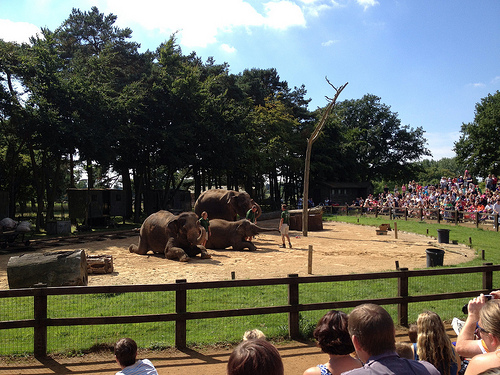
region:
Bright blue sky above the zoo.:
[387, 12, 469, 84]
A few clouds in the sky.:
[242, 4, 330, 50]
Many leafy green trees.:
[32, 6, 299, 188]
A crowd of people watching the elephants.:
[367, 171, 498, 223]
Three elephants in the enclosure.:
[122, 178, 281, 273]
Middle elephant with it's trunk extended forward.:
[202, 212, 282, 253]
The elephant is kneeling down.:
[124, 190, 213, 268]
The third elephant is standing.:
[193, 178, 264, 220]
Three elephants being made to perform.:
[125, 174, 280, 275]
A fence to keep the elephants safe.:
[93, 264, 302, 349]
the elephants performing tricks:
[127, 188, 278, 260]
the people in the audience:
[112, 166, 498, 373]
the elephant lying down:
[127, 208, 210, 261]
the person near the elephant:
[197, 210, 211, 245]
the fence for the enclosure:
[0, 201, 498, 361]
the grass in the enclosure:
[1, 205, 498, 354]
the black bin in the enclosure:
[425, 245, 443, 265]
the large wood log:
[7, 249, 89, 287]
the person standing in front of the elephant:
[279, 203, 292, 249]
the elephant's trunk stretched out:
[259, 226, 281, 233]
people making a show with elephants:
[81, 157, 394, 368]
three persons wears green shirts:
[194, 195, 299, 260]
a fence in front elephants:
[28, 172, 422, 312]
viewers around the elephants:
[0, 148, 499, 373]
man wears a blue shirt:
[339, 302, 419, 374]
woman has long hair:
[405, 307, 457, 372]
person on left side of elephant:
[120, 198, 215, 268]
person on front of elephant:
[210, 202, 297, 252]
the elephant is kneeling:
[128, 203, 208, 264]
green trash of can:
[418, 240, 451, 272]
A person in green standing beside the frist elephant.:
[196, 211, 211, 246]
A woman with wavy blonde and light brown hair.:
[409, 311, 463, 374]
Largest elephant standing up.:
[189, 189, 261, 221]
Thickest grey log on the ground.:
[8, 249, 86, 288]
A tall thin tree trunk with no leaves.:
[301, 76, 350, 238]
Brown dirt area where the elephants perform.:
[0, 215, 470, 291]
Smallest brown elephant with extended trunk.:
[198, 217, 283, 249]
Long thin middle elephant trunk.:
[256, 228, 283, 235]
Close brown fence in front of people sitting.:
[0, 262, 499, 360]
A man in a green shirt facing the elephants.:
[278, 202, 293, 250]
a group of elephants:
[127, 182, 290, 266]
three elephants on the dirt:
[113, 180, 291, 275]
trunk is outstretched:
[255, 223, 281, 235]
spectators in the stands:
[343, 170, 499, 234]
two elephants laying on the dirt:
[120, 206, 287, 270]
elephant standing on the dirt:
[191, 190, 264, 234]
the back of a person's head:
[224, 337, 274, 374]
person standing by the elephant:
[121, 191, 226, 272]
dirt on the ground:
[0, 214, 478, 285]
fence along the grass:
[0, 253, 498, 365]